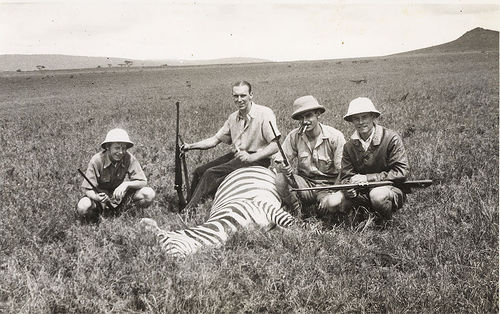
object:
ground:
[0, 49, 499, 313]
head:
[343, 97, 379, 136]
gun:
[286, 175, 434, 193]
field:
[0, 52, 499, 314]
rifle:
[170, 98, 194, 212]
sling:
[177, 134, 192, 206]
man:
[317, 96, 409, 225]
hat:
[288, 95, 325, 121]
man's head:
[296, 111, 317, 131]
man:
[174, 78, 286, 214]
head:
[101, 127, 133, 162]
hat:
[340, 95, 382, 124]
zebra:
[139, 165, 331, 265]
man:
[268, 94, 346, 219]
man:
[73, 127, 155, 222]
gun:
[265, 121, 305, 221]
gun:
[73, 167, 123, 220]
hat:
[97, 128, 134, 152]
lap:
[367, 185, 396, 204]